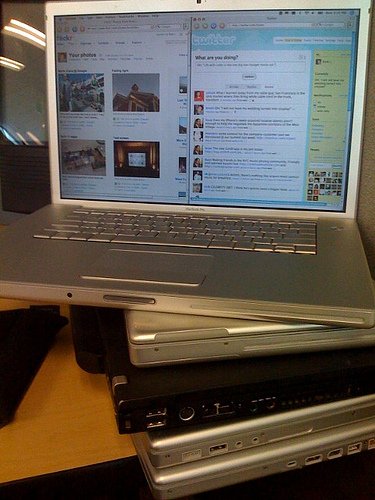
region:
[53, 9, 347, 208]
the laptop screen is on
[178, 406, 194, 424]
round power plug hole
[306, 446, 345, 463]
USB inputs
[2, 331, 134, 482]
a light wooden desk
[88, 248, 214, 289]
a touch pad on the laptop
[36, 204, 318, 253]
the keyboard is silver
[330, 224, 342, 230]
a power button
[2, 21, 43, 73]
a light reflection on the glass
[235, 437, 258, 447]
headphone holes on the computer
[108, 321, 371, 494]
a stack of laptops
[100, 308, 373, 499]
stack of closed laptops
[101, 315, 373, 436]
black laptop between silver laptops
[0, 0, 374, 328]
open laptop on stack of laptops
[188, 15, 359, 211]
Twitter open in one window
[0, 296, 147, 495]
wooden table under laptops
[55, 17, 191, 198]
flickr open in left window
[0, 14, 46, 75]
ceiling lights left of laptop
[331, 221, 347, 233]
on/off button on silver laptop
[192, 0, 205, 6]
black camera lens at top of screen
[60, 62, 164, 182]
four large photos in left window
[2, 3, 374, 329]
open silver laptop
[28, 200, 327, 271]
keyboard on silver laptop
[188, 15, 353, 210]
open twitter page on powered on laptop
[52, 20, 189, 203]
open flickr page on powered silver laptop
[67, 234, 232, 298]
square trackpad on silver laptop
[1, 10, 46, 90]
lights on ceiling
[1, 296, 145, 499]
tan wood table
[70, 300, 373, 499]
stack of laptops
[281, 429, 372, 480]
digital device input slots on side of laptop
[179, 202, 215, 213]
laptop brand name on laptop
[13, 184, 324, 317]
the laptop is silver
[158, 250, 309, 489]
a pile of laptop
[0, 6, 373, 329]
silver opened laptop on table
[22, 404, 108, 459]
light brown wooden table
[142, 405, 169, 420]
usb port on laptop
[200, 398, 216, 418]
dsl network cord port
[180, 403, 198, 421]
port for power cord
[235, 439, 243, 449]
headphone port on laptop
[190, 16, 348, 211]
google website on screen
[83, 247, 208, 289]
mouse pad on silver laptop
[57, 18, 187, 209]
flickr website pulled up on screen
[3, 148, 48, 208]
brick wall in the background